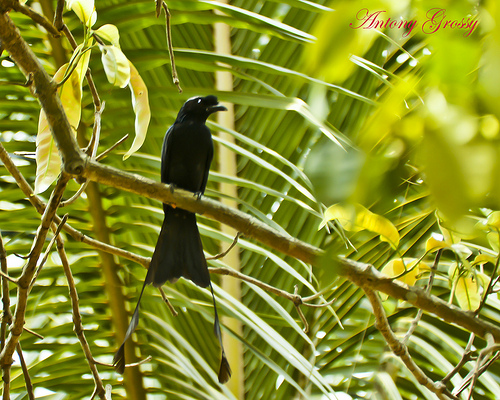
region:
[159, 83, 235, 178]
this is a bird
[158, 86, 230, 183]
the bird is black in color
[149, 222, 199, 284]
this is the tail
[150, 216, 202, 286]
the tail is long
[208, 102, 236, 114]
this is the beak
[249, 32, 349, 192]
these are the leaves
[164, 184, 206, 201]
this is the leg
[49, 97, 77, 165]
this is a branch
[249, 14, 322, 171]
the leaves are green in color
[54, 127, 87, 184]
the branch is thin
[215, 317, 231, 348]
part f a leaf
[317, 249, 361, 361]
part of a plant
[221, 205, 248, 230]
part of a branch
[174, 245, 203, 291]
part f a tail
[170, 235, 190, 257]
edge of a tail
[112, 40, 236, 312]
bird on the branch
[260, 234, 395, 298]
the branch is thin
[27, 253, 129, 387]
the leaves are thin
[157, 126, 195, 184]
the bird is black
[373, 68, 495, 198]
the leaves are blurry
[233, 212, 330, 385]
sun through the leaves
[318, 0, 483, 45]
the logo on right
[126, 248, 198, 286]
tail of the bird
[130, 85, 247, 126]
head of the bird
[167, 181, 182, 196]
foot of the bird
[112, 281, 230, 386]
long tail feathers on outside of tail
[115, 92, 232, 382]
tropical black bird on branch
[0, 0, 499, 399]
large tree branch with bird on it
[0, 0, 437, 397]
large fan leaved plant behind bird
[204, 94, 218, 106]
black furry eye ring on bird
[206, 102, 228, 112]
black bill on bird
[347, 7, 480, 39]
Red Watermark in top right corner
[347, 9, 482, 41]
Watermark by Antony Grossy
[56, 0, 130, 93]
small white circular leaves beside bird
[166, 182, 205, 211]
small red feet on bird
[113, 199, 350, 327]
A leaf on a stem.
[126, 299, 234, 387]
A leaf on a stem.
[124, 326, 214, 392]
A leaf on a stem.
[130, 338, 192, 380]
A leaf on a stem.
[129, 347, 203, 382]
A leaf on a stem.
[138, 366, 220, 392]
A leaf on a stem.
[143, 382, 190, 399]
A leaf on a stem.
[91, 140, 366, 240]
A leaf on a stem.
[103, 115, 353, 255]
A leaf on a stem.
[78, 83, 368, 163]
A leaf on a stem.